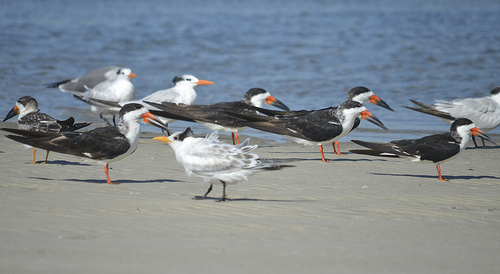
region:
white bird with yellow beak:
[146, 129, 303, 204]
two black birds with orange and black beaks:
[280, 87, 394, 162]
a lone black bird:
[346, 118, 494, 182]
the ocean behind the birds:
[2, 0, 497, 142]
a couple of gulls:
[53, 62, 222, 105]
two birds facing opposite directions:
[0, 96, 170, 162]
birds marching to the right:
[166, 70, 498, 146]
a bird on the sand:
[137, 123, 295, 208]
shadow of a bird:
[370, 166, 499, 186]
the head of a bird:
[170, 70, 220, 89]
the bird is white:
[146, 132, 276, 183]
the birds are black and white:
[217, 75, 479, 150]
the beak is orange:
[200, 72, 215, 87]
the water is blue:
[260, 31, 407, 81]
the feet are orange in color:
[75, 160, 140, 196]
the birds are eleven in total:
[8, 71, 497, 196]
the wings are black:
[395, 115, 460, 160]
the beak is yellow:
[145, 126, 171, 146]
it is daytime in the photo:
[2, 5, 497, 260]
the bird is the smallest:
[163, 125, 250, 177]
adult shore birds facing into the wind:
[60, 55, 497, 193]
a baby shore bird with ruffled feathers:
[148, 125, 294, 215]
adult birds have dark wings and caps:
[156, 85, 487, 180]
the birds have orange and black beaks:
[340, 81, 395, 133]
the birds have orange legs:
[311, 137, 454, 184]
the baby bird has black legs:
[152, 121, 292, 201]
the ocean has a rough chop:
[10, 3, 495, 125]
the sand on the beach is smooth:
[5, 117, 497, 269]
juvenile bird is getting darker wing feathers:
[5, 91, 92, 166]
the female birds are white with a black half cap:
[97, 65, 215, 125]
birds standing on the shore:
[13, 55, 489, 210]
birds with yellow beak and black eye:
[146, 121, 286, 207]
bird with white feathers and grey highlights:
[151, 120, 286, 205]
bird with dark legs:
[140, 110, 291, 210]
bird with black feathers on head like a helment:
[331, 95, 492, 185]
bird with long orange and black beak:
[430, 105, 491, 157]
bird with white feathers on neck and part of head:
[330, 110, 481, 176]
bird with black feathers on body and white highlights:
[345, 111, 490, 176]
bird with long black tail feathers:
[335, 130, 430, 165]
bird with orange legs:
[415, 145, 456, 195]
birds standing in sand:
[67, 80, 465, 197]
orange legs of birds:
[314, 139, 346, 162]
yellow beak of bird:
[147, 134, 174, 149]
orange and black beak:
[357, 107, 388, 129]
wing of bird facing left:
[191, 143, 258, 177]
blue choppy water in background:
[237, 22, 402, 72]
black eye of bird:
[169, 133, 184, 145]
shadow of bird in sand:
[396, 172, 486, 184]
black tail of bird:
[337, 134, 399, 158]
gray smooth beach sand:
[45, 200, 160, 241]